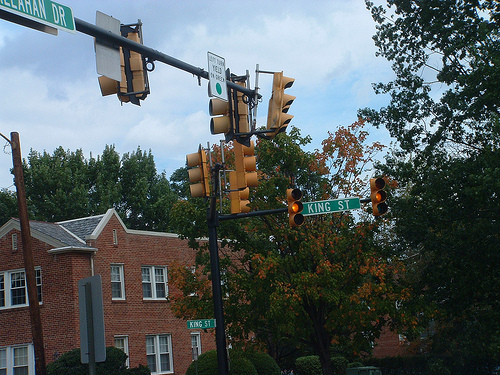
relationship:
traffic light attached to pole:
[252, 66, 297, 139] [74, 17, 263, 101]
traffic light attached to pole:
[208, 81, 253, 144] [74, 17, 263, 101]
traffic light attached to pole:
[98, 20, 149, 108] [74, 17, 263, 101]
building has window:
[0, 208, 424, 374] [108, 263, 125, 301]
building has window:
[0, 208, 424, 374] [141, 266, 155, 301]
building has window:
[0, 208, 424, 374] [152, 265, 167, 300]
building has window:
[0, 208, 424, 374] [146, 335, 157, 374]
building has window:
[0, 208, 424, 374] [157, 335, 173, 374]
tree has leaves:
[164, 117, 422, 374] [160, 118, 433, 353]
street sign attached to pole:
[0, 1, 76, 29] [74, 17, 263, 101]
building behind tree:
[0, 208, 424, 374] [164, 117, 422, 374]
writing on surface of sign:
[208, 53, 226, 83] [206, 52, 230, 103]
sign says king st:
[302, 195, 362, 215] [306, 199, 351, 213]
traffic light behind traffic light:
[228, 168, 252, 213] [233, 139, 261, 189]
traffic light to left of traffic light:
[183, 144, 212, 199] [233, 139, 261, 189]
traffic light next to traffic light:
[208, 81, 253, 144] [252, 66, 297, 139]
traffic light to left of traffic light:
[98, 20, 149, 108] [208, 81, 253, 144]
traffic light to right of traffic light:
[369, 177, 389, 217] [285, 186, 306, 231]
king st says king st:
[186, 319, 216, 328] [188, 319, 210, 328]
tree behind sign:
[164, 117, 422, 374] [302, 195, 362, 215]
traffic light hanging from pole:
[285, 186, 306, 231] [215, 205, 289, 223]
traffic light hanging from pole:
[369, 177, 389, 217] [215, 205, 289, 223]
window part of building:
[6, 270, 29, 305] [0, 208, 424, 374]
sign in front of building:
[75, 273, 107, 374] [0, 208, 424, 374]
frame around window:
[6, 344, 34, 374] [14, 347, 28, 374]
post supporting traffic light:
[206, 189, 377, 373] [228, 168, 252, 213]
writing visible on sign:
[208, 53, 226, 83] [206, 52, 230, 103]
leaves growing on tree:
[302, 117, 412, 313] [164, 117, 422, 374]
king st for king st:
[186, 319, 216, 328] [188, 319, 210, 328]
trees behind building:
[0, 144, 216, 232] [0, 208, 424, 374]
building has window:
[0, 208, 424, 374] [1, 347, 8, 373]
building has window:
[0, 208, 424, 374] [191, 332, 199, 361]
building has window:
[0, 208, 424, 374] [117, 337, 125, 352]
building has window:
[0, 208, 424, 374] [6, 270, 29, 305]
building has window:
[0, 208, 424, 374] [14, 347, 28, 374]